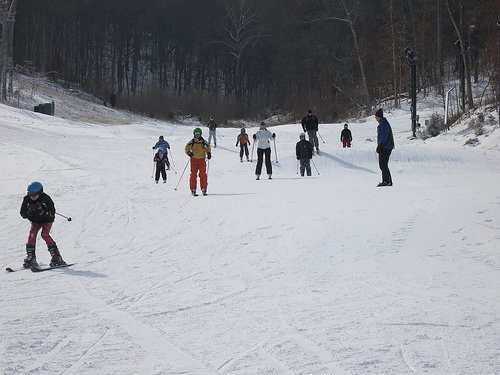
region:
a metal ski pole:
[173, 157, 192, 191]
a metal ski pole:
[205, 156, 212, 176]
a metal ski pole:
[52, 209, 69, 223]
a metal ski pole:
[271, 137, 280, 164]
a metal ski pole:
[249, 139, 256, 161]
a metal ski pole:
[309, 156, 319, 174]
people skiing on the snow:
[7, 91, 414, 278]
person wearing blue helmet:
[0, 174, 85, 282]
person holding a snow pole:
[9, 172, 84, 274]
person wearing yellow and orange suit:
[179, 121, 217, 206]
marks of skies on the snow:
[25, 286, 462, 373]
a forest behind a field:
[3, 0, 483, 113]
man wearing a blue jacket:
[365, 97, 397, 195]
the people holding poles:
[246, 102, 332, 192]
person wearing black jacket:
[286, 129, 323, 180]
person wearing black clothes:
[336, 116, 360, 153]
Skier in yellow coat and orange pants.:
[184, 127, 211, 192]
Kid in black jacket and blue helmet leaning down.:
[19, 182, 64, 267]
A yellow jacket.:
[184, 136, 211, 158]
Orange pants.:
[189, 157, 208, 192]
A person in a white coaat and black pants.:
[252, 122, 274, 178]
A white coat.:
[252, 131, 273, 151]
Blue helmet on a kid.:
[25, 181, 42, 199]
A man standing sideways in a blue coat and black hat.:
[373, 107, 394, 186]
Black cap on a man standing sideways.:
[372, 107, 384, 119]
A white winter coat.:
[252, 129, 272, 150]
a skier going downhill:
[5, 181, 74, 273]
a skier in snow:
[152, 147, 177, 185]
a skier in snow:
[151, 135, 176, 167]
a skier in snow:
[203, 114, 224, 146]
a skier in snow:
[234, 127, 252, 163]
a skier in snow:
[247, 121, 279, 181]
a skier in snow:
[294, 132, 321, 177]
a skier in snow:
[300, 109, 324, 155]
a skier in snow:
[339, 122, 354, 149]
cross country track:
[19, 76, 495, 353]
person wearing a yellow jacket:
[173, 108, 220, 228]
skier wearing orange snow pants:
[180, 108, 246, 235]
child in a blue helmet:
[13, 163, 93, 298]